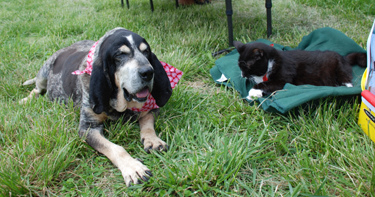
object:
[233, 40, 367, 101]
cat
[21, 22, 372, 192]
dogandcat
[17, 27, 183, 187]
dog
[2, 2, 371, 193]
grass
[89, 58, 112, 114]
ear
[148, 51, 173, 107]
ear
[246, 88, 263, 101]
paws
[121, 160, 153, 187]
paws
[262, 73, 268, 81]
collar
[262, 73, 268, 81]
ribbon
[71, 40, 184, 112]
scarf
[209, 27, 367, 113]
blanket